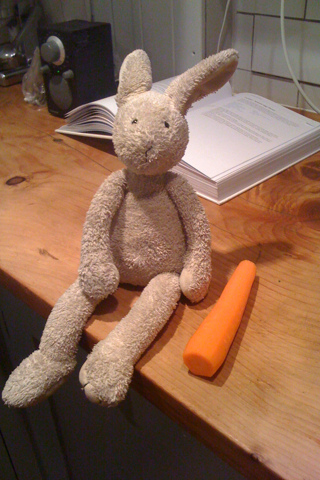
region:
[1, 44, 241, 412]
a fuzzy stuffed rabbit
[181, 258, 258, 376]
a peeled orange carrot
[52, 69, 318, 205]
an open hard covered book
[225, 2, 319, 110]
white tiles on the wall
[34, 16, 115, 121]
a speaker behind the rabbit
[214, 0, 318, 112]
white wires hanging on the wall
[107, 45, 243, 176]
the toy rabbits head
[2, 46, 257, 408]
a toy rabbit is sitting next to a carrot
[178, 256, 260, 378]
the peeled carrot is orange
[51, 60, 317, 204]
the book has pages with words on it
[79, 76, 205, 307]
this is a rabbit doll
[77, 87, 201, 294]
the doll is sitted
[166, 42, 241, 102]
this is the ear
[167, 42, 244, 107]
the ear is big in size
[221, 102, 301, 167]
this is a book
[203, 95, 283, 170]
the book is open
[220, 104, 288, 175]
the pages are white in color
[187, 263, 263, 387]
this is a carrot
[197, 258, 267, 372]
the carrot is big in size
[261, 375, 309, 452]
this is the table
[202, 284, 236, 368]
a portion of large carrot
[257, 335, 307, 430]
a portion of the brown table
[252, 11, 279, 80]
ceramic tiling on the wall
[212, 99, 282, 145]
writing on the page in book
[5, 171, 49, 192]
a knotted pattern in the wood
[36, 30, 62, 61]
a silver knob on black speaker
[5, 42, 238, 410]
a stuffed bunny on table near carrot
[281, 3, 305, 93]
white wire hanging near the wall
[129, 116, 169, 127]
both eyes on the stuffed animal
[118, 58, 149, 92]
floppy ear on the stuffed animal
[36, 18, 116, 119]
An audio speaker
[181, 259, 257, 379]
An orange carrot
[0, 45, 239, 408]
A rabbit stuffed animal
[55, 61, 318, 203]
A large white open book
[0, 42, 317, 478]
A wooden table with multiple items on it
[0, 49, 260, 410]
A stuffed rabbit sitting next to a carrot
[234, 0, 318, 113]
A white tile wall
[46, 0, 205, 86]
A white wood panel wall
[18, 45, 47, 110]
A little plastic baggie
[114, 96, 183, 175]
The face of a stuffed rabbit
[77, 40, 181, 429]
This is a bunny rabbit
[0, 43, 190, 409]
This is a stuffed animal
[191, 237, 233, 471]
This is a carrot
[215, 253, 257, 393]
The carrot is orange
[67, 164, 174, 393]
The rabbit is light brown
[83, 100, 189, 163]
The rabbit has black eyes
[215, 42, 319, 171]
This is an open book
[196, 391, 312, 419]
This is a wooden table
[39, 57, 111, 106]
This is a speaker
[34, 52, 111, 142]
The speaker is black